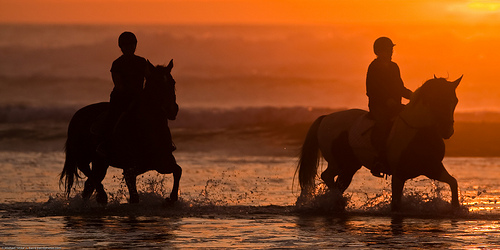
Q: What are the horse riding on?
A: Water.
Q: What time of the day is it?
A: Sunset.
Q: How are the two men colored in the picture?
A: Black.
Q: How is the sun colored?
A: Orange and yellow.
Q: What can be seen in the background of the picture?
A: Waves.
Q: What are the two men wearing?
A: Helmets.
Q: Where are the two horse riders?
A: In the ocean.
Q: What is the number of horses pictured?
A: 2.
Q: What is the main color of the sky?
A: ORange.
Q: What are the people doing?
A: Riding horses.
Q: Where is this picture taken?
A: At the beach.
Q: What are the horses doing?
A: Walking in the water.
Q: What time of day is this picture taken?
A: Sunset.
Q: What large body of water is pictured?
A: Ocean.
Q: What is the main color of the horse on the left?
A: Black.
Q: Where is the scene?
A: On the beach.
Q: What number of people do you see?
A: 2 people.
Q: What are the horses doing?
A: Walking in the water.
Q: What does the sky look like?
A: The sky is orange.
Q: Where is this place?
A: The beach.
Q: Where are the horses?
A: In the water.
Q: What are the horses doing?
A: Wading through the water.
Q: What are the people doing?
A: Riding.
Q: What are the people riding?
A: Horses.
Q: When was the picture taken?
A: At sunset.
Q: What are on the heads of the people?
A: Helmets.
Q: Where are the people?
A: On the horses.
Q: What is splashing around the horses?
A: Water.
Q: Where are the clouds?
A: In the sky.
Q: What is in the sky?
A: Clouds.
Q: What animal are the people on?
A: Horses.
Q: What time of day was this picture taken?
A: Sunset.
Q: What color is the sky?
A: Orange.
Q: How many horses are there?
A: Two.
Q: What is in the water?
A: The horses.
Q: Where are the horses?
A: In the water.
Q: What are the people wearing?
A: Helmets.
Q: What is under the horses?
A: Water.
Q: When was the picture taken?
A: Daytime.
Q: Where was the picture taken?
A: At the beach.